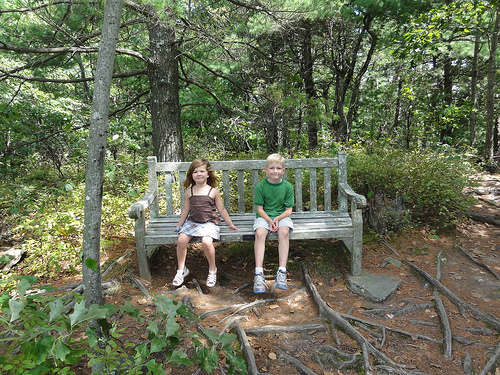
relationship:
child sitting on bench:
[172, 158, 239, 287] [131, 147, 370, 289]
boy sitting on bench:
[252, 153, 294, 294] [131, 147, 370, 289]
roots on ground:
[1, 162, 498, 373] [2, 151, 495, 371]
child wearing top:
[172, 158, 239, 287] [186, 185, 216, 222]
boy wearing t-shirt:
[252, 153, 297, 292] [237, 147, 304, 224]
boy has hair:
[252, 153, 294, 294] [263, 155, 285, 170]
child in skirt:
[172, 158, 239, 287] [178, 218, 221, 241]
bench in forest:
[128, 151, 368, 281] [0, 0, 498, 374]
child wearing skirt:
[172, 158, 239, 287] [173, 221, 218, 243]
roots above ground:
[0, 210, 500, 373] [2, 151, 495, 371]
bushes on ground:
[358, 138, 462, 224] [2, 151, 495, 371]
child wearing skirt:
[172, 158, 239, 287] [180, 216, 220, 238]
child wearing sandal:
[172, 158, 239, 287] [204, 269, 217, 289]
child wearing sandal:
[172, 158, 239, 287] [172, 264, 190, 287]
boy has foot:
[252, 153, 294, 294] [275, 272, 288, 292]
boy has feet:
[252, 153, 294, 294] [251, 266, 268, 292]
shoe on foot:
[275, 269, 289, 291] [275, 272, 288, 292]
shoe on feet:
[253, 273, 267, 298] [251, 266, 268, 292]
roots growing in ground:
[0, 210, 500, 373] [2, 151, 495, 371]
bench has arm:
[131, 147, 370, 289] [336, 178, 372, 210]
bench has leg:
[131, 147, 370, 289] [351, 205, 365, 279]